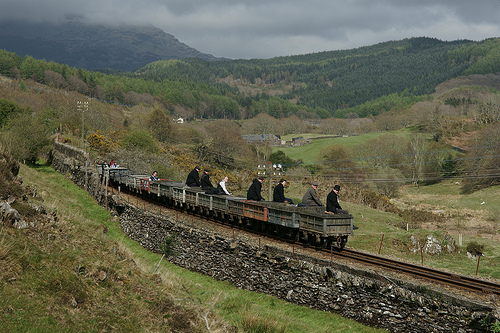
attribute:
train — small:
[100, 153, 354, 248]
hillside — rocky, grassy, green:
[3, 145, 269, 332]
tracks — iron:
[110, 183, 496, 297]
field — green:
[6, 130, 499, 329]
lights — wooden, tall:
[73, 93, 94, 151]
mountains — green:
[7, 3, 493, 127]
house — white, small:
[175, 115, 189, 127]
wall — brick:
[121, 207, 491, 330]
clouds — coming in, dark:
[3, 5, 494, 54]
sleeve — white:
[219, 180, 230, 195]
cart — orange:
[241, 199, 270, 221]